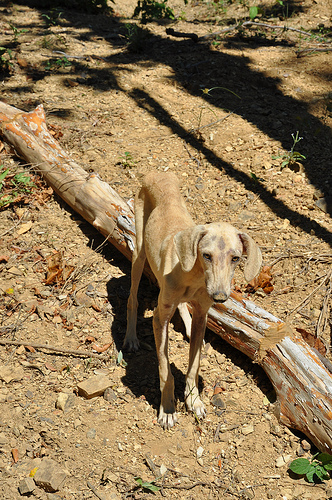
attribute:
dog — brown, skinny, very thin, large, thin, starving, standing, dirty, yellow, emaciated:
[121, 172, 261, 427]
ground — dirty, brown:
[0, 0, 331, 499]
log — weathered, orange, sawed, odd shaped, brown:
[0, 101, 331, 455]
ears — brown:
[171, 222, 263, 282]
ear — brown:
[173, 225, 209, 273]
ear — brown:
[239, 233, 262, 281]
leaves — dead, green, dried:
[0, 0, 331, 499]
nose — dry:
[212, 292, 228, 302]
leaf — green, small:
[134, 478, 160, 493]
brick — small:
[77, 374, 116, 398]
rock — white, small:
[241, 426, 253, 435]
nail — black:
[161, 424, 166, 432]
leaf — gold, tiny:
[159, 462, 167, 477]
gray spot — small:
[217, 235, 226, 251]